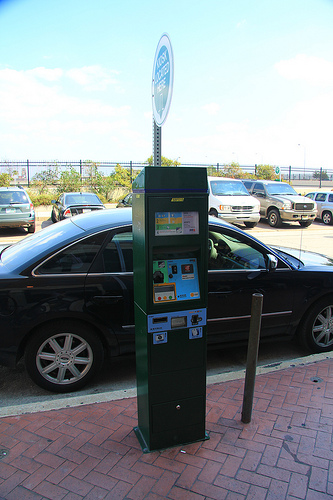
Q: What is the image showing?
A: It is showing a sidewalk.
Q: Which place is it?
A: It is a sidewalk.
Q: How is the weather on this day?
A: It is clear.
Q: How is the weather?
A: It is clear.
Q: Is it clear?
A: Yes, it is clear.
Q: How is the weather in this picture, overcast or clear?
A: It is clear.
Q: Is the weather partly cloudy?
A: No, it is clear.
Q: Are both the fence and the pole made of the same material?
A: Yes, both the fence and the pole are made of metal.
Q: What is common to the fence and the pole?
A: The material, both the fence and the pole are metallic.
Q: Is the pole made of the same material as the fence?
A: Yes, both the pole and the fence are made of metal.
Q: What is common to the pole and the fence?
A: The material, both the pole and the fence are metallic.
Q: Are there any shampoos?
A: No, there are no shampoos.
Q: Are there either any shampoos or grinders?
A: No, there are no shampoos or grinders.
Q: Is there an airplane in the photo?
A: No, there are no airplanes.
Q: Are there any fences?
A: Yes, there is a fence.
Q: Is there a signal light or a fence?
A: Yes, there is a fence.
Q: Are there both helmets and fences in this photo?
A: No, there is a fence but no helmets.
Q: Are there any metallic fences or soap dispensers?
A: Yes, there is a metal fence.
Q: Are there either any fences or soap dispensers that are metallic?
A: Yes, the fence is metallic.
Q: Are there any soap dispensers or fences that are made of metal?
A: Yes, the fence is made of metal.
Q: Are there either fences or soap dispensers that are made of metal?
A: Yes, the fence is made of metal.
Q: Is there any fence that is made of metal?
A: Yes, there is a fence that is made of metal.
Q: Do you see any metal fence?
A: Yes, there is a fence that is made of metal.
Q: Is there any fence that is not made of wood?
A: Yes, there is a fence that is made of metal.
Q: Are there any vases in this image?
A: No, there are no vases.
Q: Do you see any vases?
A: No, there are no vases.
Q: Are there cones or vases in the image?
A: No, there are no vases or cones.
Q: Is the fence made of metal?
A: Yes, the fence is made of metal.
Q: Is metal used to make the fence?
A: Yes, the fence is made of metal.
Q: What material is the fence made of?
A: The fence is made of metal.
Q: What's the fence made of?
A: The fence is made of metal.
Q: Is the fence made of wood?
A: No, the fence is made of metal.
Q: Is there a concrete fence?
A: No, there is a fence but it is made of metal.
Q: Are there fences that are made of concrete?
A: No, there is a fence but it is made of metal.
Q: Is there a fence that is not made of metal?
A: No, there is a fence but it is made of metal.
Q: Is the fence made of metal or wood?
A: The fence is made of metal.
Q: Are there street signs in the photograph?
A: Yes, there is a street sign.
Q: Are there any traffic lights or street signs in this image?
A: Yes, there is a street sign.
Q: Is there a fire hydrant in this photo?
A: No, there are no fire hydrants.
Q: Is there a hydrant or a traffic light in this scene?
A: No, there are no fire hydrants or traffic lights.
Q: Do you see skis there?
A: No, there are no skis.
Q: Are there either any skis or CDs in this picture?
A: No, there are no skis or cds.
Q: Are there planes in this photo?
A: No, there are no planes.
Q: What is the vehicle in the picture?
A: The vehicle is a car.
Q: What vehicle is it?
A: The vehicle is a car.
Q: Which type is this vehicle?
A: That is a car.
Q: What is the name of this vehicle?
A: That is a car.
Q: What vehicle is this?
A: That is a car.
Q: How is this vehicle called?
A: That is a car.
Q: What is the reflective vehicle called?
A: The vehicle is a car.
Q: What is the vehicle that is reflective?
A: The vehicle is a car.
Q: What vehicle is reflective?
A: The vehicle is a car.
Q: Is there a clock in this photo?
A: No, there are no clocks.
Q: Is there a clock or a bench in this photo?
A: No, there are no clocks or benches.